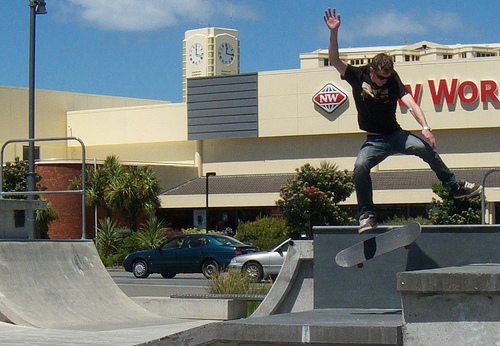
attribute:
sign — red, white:
[313, 80, 346, 115]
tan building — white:
[66, 55, 499, 235]